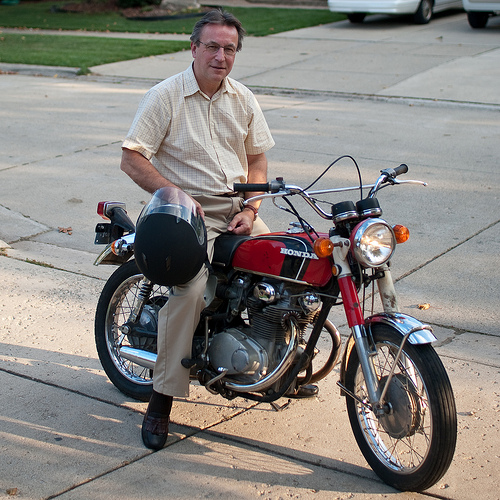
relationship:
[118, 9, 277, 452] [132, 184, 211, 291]
man holding helmet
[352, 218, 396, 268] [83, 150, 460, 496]
headlight of motorcycle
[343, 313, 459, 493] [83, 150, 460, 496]
wheel of motorcycle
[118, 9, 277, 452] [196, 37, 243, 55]
man wearing glasses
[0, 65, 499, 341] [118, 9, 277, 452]
street behind man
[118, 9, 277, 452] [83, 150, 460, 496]
man on top of motorcycle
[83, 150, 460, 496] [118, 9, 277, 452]
motorcycle under man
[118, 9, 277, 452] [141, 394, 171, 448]
man wearing shoe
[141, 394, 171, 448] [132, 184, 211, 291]
shoe under helmet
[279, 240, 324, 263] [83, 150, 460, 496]
honda across motorcycle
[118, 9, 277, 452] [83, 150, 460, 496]
man sitting on motorcycle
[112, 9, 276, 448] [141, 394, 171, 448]
man wearing shoe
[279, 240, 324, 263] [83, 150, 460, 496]
honda on motorcycle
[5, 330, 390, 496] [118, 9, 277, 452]
shadow of man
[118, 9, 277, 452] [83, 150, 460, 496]
man on motorcycle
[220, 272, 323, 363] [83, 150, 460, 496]
engine of motorcycle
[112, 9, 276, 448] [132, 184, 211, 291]
man holding helmet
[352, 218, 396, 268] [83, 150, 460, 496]
headlight on motorcycle